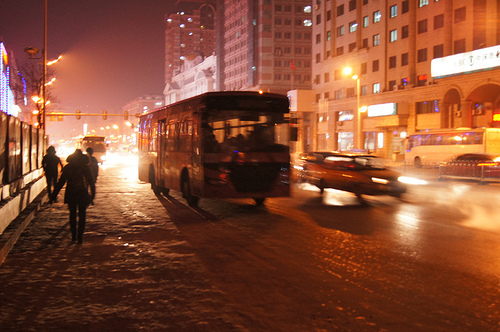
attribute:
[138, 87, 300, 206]
bus — driving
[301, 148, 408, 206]
car — in motion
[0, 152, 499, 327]
road — wet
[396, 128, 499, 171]
bus — white, parked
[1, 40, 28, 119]
lights — neon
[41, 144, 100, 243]
people — walking in dark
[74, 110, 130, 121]
traffic lights — signal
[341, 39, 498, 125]
several lights — street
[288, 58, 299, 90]
flag — red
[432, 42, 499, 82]
sign — white, lit up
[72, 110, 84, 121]
stoplight — used for traffic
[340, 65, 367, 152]
streetlight — lit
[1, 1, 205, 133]
sky — dark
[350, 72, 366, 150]
pole — yellow